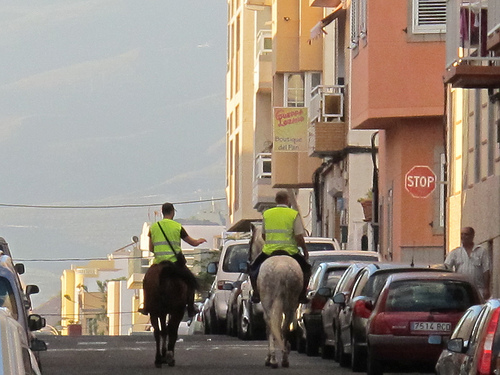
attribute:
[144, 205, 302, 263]
vests — fluorescent green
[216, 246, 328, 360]
horse —  grey , white 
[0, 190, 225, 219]
line — utility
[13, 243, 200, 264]
line — utility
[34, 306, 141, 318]
line — utility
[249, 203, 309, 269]
vest — green,  grey 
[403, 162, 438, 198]
street sign — white, red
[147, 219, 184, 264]
vest — yellow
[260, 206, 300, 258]
vest — yellow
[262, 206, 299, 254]
vest — neon green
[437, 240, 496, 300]
shirt — button down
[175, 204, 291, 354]
van — white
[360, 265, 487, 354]
hatchback — red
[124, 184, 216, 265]
vest — neon green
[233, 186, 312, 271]
man — gray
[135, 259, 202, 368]
horse — brown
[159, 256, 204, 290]
tail — black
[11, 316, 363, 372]
road — downhill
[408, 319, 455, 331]
license plates — eurpean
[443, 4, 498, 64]
railing — grey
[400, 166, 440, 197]
sign — stop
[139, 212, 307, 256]
vests — bright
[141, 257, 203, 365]
horse — black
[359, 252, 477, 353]
car — red